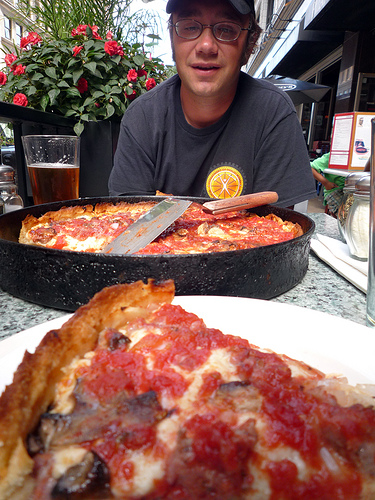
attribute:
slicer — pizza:
[96, 186, 280, 254]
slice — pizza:
[1, 274, 363, 496]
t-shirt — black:
[104, 71, 320, 208]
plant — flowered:
[1, 21, 159, 122]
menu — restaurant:
[326, 112, 353, 171]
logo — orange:
[205, 166, 245, 200]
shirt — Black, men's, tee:
[105, 70, 317, 211]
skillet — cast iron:
[8, 242, 330, 304]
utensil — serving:
[100, 190, 282, 258]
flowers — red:
[17, 28, 39, 47]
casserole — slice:
[4, 281, 371, 497]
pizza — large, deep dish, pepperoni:
[1, 195, 313, 310]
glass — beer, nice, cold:
[19, 135, 80, 207]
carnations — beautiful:
[2, 24, 164, 137]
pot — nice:
[0, 100, 118, 205]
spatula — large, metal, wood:
[100, 190, 277, 252]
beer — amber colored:
[21, 134, 82, 204]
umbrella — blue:
[258, 72, 330, 104]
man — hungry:
[108, 0, 319, 210]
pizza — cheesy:
[0, 274, 373, 498]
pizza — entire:
[18, 203, 303, 254]